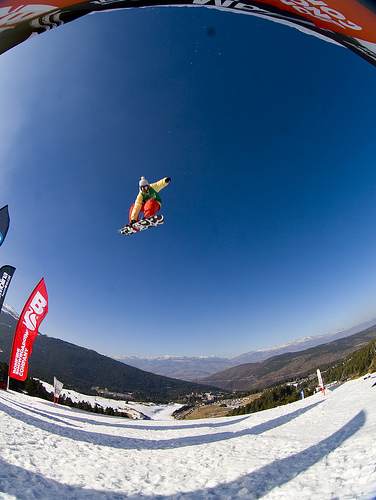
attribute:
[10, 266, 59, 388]
flag — red, sponsorship flag, white, tall, standing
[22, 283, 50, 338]
letters — white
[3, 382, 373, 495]
snow — white, snowboaring area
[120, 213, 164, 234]
snowboard — black, white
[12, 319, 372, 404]
mountains — snow capped, snow covered, brown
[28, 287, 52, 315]
b — white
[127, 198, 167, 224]
pants — orange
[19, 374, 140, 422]
trees — evergreen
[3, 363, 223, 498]
path — snowy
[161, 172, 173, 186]
glove — black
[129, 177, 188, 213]
jacket — puffer jacket